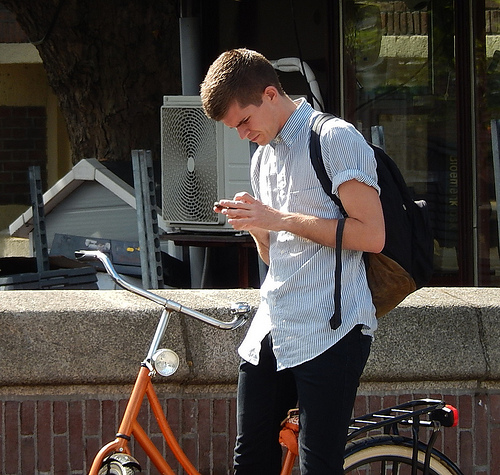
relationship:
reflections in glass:
[340, 6, 477, 291] [338, 8, 471, 286]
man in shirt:
[149, 35, 433, 468] [228, 100, 388, 383]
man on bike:
[149, 35, 433, 468] [76, 249, 467, 470]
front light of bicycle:
[150, 349, 182, 376] [58, 242, 470, 472]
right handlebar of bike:
[82, 234, 135, 288] [76, 249, 467, 470]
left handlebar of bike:
[193, 279, 247, 339] [52, 231, 496, 472]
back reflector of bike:
[430, 397, 473, 427] [52, 231, 496, 472]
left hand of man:
[221, 193, 275, 240] [191, 35, 390, 468]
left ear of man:
[264, 76, 283, 108] [191, 35, 390, 468]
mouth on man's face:
[248, 129, 261, 148] [215, 92, 280, 152]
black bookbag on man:
[319, 125, 449, 330] [180, 16, 398, 473]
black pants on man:
[224, 294, 389, 473] [193, 44, 376, 465]